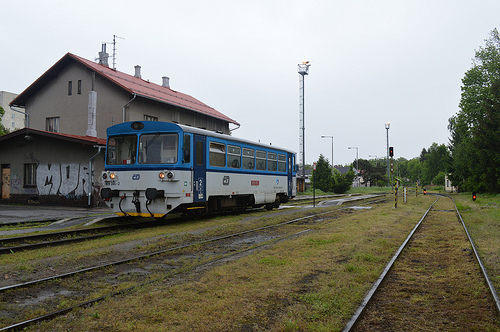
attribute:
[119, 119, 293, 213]
train car — passenger, white, blue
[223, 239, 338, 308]
grass — patchy, green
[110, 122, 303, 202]
car — blue, white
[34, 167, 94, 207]
graffiti — painted, large piece, large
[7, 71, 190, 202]
building — small, two story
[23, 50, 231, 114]
roof — red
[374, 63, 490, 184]
trees — green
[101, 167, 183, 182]
headlights — set, round, on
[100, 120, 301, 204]
train — multi-colored, stationary, long, blue, white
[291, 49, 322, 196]
tower — tall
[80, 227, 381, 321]
tracks — covered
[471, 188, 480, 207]
signal — red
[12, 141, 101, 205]
wall — large, white, graffitied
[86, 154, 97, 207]
water drain — white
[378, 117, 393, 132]
street lamp — off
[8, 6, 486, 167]
sky — overcast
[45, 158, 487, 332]
ground — wet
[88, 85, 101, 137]
chimney — tall, stack, skinny, long, white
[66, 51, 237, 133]
rooftop — triangle shaped, red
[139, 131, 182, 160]
window — rectangle shaped, clear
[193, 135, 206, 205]
door — dark blue, blue, rectangle, long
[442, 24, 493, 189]
tree — evergreen, full, green, bushy, big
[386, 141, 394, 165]
traffic light — red, rectangle shaped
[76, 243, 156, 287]
mud — patches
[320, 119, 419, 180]
streetlights — few